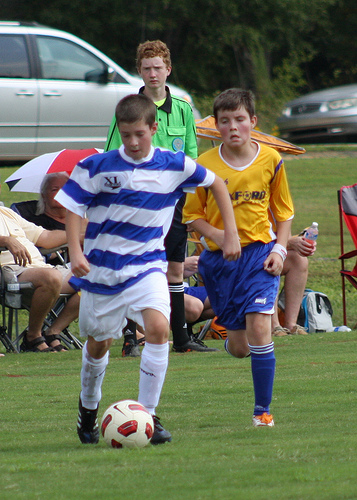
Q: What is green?
A: Grass.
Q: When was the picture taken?
A: Daytime.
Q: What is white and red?
A: Soccer ball.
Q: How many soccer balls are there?
A: One.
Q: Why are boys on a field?
A: To play soccer.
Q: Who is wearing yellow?
A: Boy on right.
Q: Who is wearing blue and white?
A: Boy on left.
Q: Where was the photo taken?
A: On a field.